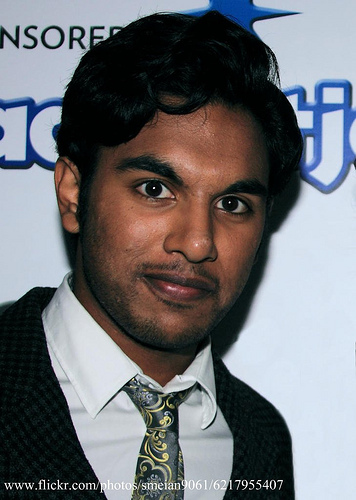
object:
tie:
[122, 377, 199, 500]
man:
[0, 10, 305, 499]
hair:
[54, 8, 304, 227]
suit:
[0, 281, 293, 500]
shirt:
[40, 271, 235, 499]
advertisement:
[0, 1, 354, 199]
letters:
[0, 24, 27, 51]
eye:
[130, 173, 179, 204]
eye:
[213, 189, 253, 220]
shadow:
[211, 171, 299, 361]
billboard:
[0, 1, 355, 498]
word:
[0, 79, 355, 195]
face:
[80, 95, 272, 349]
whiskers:
[80, 206, 239, 351]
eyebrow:
[111, 149, 185, 185]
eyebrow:
[222, 178, 272, 200]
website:
[3, 473, 286, 500]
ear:
[47, 147, 83, 239]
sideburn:
[75, 166, 93, 226]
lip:
[147, 271, 213, 292]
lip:
[146, 281, 212, 303]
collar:
[41, 272, 220, 433]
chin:
[129, 307, 215, 358]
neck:
[72, 247, 206, 386]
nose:
[163, 206, 221, 270]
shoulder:
[231, 375, 296, 453]